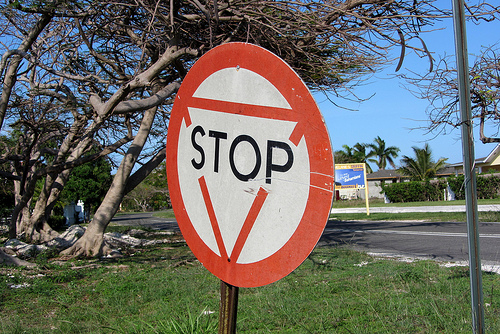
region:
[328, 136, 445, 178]
tall green palm trees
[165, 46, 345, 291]
circular stop sign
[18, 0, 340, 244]
large tree with no leaves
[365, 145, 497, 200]
house in the background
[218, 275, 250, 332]
rusty pole attached to stop sign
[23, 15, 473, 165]
bright blue sky with no clouds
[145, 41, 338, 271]
red, white and black sign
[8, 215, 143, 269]
white rocks near tree trunks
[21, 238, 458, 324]
patch of green grass on roadside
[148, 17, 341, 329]
stop sign on a pole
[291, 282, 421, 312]
green grass on the ground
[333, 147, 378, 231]
sign on the road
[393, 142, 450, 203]
palm tree across the street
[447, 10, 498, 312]
pole in the grass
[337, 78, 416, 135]
blue sky in the distance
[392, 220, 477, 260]
paved road of a street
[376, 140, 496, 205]
houses across the street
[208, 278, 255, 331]
pole of a stop sign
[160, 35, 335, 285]
red and white stop sign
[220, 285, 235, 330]
pole displaying stop sign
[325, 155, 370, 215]
sign for local business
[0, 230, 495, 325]
grass withe patches of snow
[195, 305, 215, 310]
a patch of snow on grass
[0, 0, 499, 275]
whole bunch of bare trees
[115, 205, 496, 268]
paved street in neighborhood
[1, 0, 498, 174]
clear sky during day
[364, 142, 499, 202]
neighborhood dwelling with sign in front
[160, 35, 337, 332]
A stop sign in a suburban area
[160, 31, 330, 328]
A stop sign in a suburban area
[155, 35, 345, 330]
A stop sign in a suburban area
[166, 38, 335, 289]
circle shape sign board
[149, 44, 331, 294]
circle shape sign board with red color border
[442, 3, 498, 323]
grey color metal pole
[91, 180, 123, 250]
trunk of the tree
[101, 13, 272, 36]
branches of the tree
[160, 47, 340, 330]
stop sign board with metal post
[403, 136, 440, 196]
coconut tree near the house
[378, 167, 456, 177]
roof of the building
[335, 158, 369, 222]
metal pole with advertisement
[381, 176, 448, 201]
plants and leaves in front of the house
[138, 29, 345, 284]
a red and white sign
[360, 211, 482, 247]
lines on the road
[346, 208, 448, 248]
shadows on the road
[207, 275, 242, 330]
pole for the sign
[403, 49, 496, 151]
branches void of leaves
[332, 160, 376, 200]
sign in the background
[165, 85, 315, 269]
triangle on the sign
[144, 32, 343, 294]
circle with triangle in it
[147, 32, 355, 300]
circle with triangle in it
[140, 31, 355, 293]
circle with triangle in it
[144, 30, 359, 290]
circle with triangle in it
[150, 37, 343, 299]
circle with triangle in it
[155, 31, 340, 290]
circle with triangle in it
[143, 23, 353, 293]
circle with triangle in it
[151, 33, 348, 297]
circle with triangle in it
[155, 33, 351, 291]
circle with triangle in it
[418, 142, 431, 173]
green leaves on the tree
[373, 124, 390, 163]
green leaves on the tree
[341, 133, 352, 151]
green leaves on the tree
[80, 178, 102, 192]
green leaves on the tree